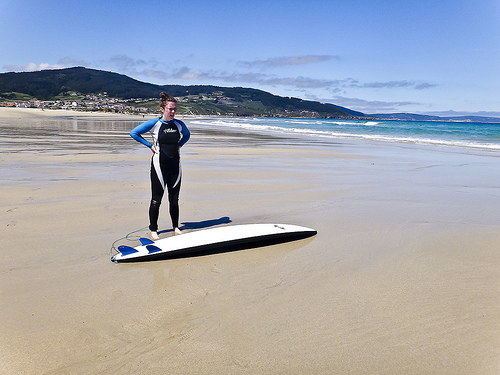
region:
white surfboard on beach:
[106, 215, 316, 267]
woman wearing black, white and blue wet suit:
[126, 90, 206, 237]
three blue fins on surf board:
[105, 235, 190, 263]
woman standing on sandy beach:
[126, 83, 217, 274]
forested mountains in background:
[5, 60, 496, 120]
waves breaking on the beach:
[201, 116, 498, 159]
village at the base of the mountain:
[11, 92, 138, 119]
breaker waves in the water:
[293, 117, 393, 129]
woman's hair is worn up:
[156, 88, 181, 125]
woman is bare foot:
[140, 83, 197, 240]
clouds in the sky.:
[267, 52, 317, 68]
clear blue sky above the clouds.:
[378, 14, 443, 33]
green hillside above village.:
[72, 73, 106, 80]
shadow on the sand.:
[189, 209, 236, 226]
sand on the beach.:
[29, 261, 87, 316]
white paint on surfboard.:
[203, 225, 270, 247]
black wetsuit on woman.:
[165, 147, 173, 174]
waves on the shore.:
[380, 131, 468, 151]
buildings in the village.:
[79, 100, 121, 110]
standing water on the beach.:
[76, 122, 124, 132]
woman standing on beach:
[94, 82, 319, 264]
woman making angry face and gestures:
[131, 90, 200, 155]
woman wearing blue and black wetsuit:
[148, 105, 182, 232]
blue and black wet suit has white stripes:
[143, 122, 185, 195]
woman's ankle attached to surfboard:
[108, 217, 170, 262]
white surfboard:
[104, 220, 333, 260]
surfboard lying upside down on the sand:
[94, 210, 354, 285]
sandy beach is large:
[63, 124, 452, 335]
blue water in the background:
[264, 93, 478, 178]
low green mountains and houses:
[17, 60, 372, 132]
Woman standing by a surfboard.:
[104, 88, 324, 265]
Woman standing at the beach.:
[28, 67, 486, 307]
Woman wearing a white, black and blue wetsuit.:
[121, 87, 204, 235]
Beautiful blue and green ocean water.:
[270, 112, 499, 152]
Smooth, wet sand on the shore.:
[362, 198, 495, 338]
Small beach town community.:
[10, 83, 147, 118]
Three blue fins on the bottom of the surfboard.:
[117, 235, 164, 259]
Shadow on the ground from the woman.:
[170, 211, 233, 233]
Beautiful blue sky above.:
[62, 10, 440, 51]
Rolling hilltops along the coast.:
[12, 58, 242, 95]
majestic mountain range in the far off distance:
[37, 52, 114, 90]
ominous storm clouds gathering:
[248, 52, 344, 89]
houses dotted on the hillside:
[193, 86, 238, 103]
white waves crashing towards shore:
[209, 109, 308, 134]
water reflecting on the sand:
[43, 107, 116, 142]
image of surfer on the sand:
[118, 206, 267, 219]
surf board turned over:
[108, 213, 328, 247]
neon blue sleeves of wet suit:
[118, 114, 166, 159]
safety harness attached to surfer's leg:
[84, 216, 171, 268]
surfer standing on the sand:
[115, 64, 192, 213]